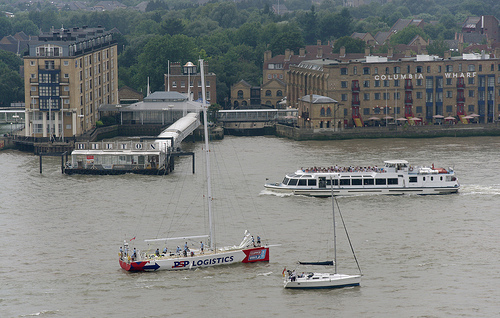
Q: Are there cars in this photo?
A: No, there are no cars.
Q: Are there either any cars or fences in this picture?
A: No, there are no cars or fences.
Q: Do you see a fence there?
A: No, there are no fences.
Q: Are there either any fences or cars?
A: No, there are no fences or cars.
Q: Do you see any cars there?
A: No, there are no cars.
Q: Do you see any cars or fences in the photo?
A: No, there are no cars or fences.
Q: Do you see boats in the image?
A: Yes, there is a boat.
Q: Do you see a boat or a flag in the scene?
A: Yes, there is a boat.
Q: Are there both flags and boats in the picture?
A: Yes, there are both a boat and a flag.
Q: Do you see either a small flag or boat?
A: Yes, there is a small boat.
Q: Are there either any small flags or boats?
A: Yes, there is a small boat.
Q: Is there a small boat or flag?
A: Yes, there is a small boat.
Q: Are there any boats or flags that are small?
A: Yes, the boat is small.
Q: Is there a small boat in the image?
A: Yes, there is a small boat.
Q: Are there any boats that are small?
A: Yes, there is a boat that is small.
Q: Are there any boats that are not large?
A: Yes, there is a small boat.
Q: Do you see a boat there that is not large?
A: Yes, there is a small boat.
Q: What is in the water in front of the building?
A: The boat is in the water.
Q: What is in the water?
A: The boat is in the water.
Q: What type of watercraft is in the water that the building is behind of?
A: The watercraft is a boat.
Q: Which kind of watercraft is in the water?
A: The watercraft is a boat.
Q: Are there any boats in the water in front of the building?
A: Yes, there is a boat in the water.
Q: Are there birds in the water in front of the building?
A: No, there is a boat in the water.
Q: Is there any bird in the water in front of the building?
A: No, there is a boat in the water.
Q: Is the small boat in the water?
A: Yes, the boat is in the water.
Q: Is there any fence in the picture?
A: No, there are no fences.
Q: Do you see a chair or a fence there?
A: No, there are no fences or chairs.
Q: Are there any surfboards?
A: No, there are no surfboards.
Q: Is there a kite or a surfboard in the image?
A: No, there are no surfboards or kites.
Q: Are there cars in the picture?
A: No, there are no cars.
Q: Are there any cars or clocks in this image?
A: No, there are no cars or clocks.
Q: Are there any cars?
A: No, there are no cars.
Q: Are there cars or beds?
A: No, there are no cars or beds.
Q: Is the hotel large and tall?
A: Yes, the hotel is large and tall.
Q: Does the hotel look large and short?
A: No, the hotel is large but tall.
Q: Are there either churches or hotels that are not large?
A: No, there is a hotel but it is large.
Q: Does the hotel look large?
A: Yes, the hotel is large.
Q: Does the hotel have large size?
A: Yes, the hotel is large.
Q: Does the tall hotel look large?
A: Yes, the hotel is large.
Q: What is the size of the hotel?
A: The hotel is large.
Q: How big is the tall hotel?
A: The hotel is large.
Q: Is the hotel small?
A: No, the hotel is large.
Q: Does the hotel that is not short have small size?
A: No, the hotel is large.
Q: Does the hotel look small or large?
A: The hotel is large.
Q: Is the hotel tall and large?
A: Yes, the hotel is tall and large.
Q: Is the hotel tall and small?
A: No, the hotel is tall but large.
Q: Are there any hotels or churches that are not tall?
A: No, there is a hotel but it is tall.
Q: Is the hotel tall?
A: Yes, the hotel is tall.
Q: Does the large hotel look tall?
A: Yes, the hotel is tall.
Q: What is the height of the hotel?
A: The hotel is tall.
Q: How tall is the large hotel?
A: The hotel is tall.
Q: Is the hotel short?
A: No, the hotel is tall.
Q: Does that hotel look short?
A: No, the hotel is tall.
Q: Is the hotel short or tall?
A: The hotel is tall.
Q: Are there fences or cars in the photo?
A: No, there are no cars or fences.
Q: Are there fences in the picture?
A: No, there are no fences.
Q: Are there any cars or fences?
A: No, there are no fences or cars.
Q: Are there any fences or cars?
A: No, there are no fences or cars.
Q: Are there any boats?
A: Yes, there is a boat.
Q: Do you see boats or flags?
A: Yes, there is a boat.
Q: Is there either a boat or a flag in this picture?
A: Yes, there is a boat.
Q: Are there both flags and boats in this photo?
A: Yes, there are both a boat and a flag.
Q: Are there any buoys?
A: No, there are no buoys.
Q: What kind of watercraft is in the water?
A: The watercraft is a boat.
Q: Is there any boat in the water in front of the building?
A: Yes, there is a boat in the water.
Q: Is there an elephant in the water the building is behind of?
A: No, there is a boat in the water.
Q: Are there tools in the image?
A: No, there are no tools.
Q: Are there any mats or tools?
A: No, there are no tools or mats.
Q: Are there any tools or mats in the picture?
A: No, there are no tools or mats.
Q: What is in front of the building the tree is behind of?
A: The water is in front of the building.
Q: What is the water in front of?
A: The water is in front of the building.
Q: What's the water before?
A: The water is in front of the building.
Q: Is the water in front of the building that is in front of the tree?
A: Yes, the water is in front of the building.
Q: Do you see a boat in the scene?
A: Yes, there is a boat.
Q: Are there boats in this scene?
A: Yes, there is a boat.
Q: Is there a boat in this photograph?
A: Yes, there is a boat.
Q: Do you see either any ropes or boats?
A: Yes, there is a boat.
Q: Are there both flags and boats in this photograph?
A: Yes, there are both a boat and a flag.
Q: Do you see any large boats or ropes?
A: Yes, there is a large boat.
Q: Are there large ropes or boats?
A: Yes, there is a large boat.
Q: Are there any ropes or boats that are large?
A: Yes, the boat is large.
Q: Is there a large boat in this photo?
A: Yes, there is a large boat.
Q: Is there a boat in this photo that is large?
A: Yes, there is a boat that is large.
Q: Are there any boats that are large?
A: Yes, there is a boat that is large.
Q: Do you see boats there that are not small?
A: Yes, there is a large boat.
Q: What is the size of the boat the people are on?
A: The boat is large.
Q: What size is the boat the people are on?
A: The boat is large.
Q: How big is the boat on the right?
A: The boat is large.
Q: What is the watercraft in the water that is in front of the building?
A: The watercraft is a boat.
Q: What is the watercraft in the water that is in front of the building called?
A: The watercraft is a boat.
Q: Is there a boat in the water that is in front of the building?
A: Yes, there is a boat in the water.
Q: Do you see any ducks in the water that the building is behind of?
A: No, there is a boat in the water.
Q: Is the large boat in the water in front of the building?
A: Yes, the boat is in the water.